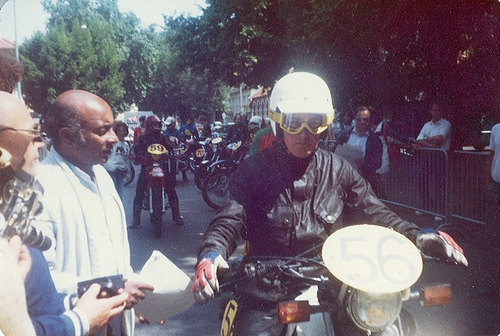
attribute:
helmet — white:
[258, 67, 335, 146]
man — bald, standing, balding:
[31, 78, 186, 335]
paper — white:
[128, 251, 199, 336]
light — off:
[344, 287, 413, 333]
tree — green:
[44, 2, 152, 140]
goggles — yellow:
[264, 98, 337, 136]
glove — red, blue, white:
[190, 249, 232, 302]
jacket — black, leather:
[201, 147, 425, 292]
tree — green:
[176, 7, 376, 93]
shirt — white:
[41, 152, 144, 315]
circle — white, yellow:
[324, 223, 427, 293]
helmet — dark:
[145, 113, 163, 137]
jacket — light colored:
[28, 156, 147, 336]